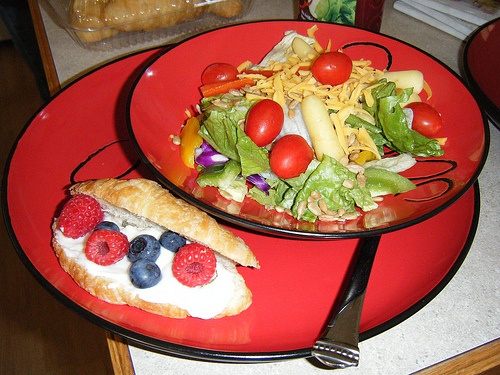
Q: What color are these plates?
A: Red.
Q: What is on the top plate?
A: A salad.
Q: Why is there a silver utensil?
A: To eat the food.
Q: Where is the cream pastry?
A: On the bottom plate.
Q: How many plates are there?
A: Two.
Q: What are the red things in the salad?
A: Grape tomatoes.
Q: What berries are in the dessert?
A: Raspberries and blueberries.